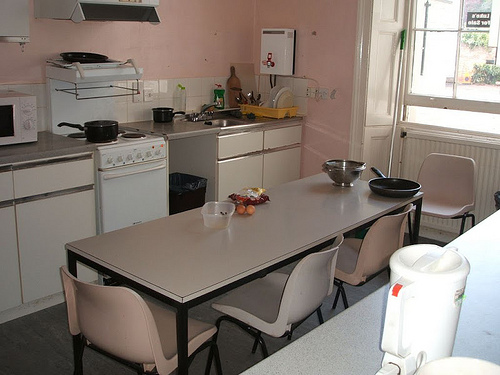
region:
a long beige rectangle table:
[55, 166, 412, 316]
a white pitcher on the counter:
[362, 227, 471, 366]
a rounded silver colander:
[314, 146, 366, 192]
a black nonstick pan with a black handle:
[365, 158, 432, 202]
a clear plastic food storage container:
[191, 196, 242, 233]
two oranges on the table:
[237, 201, 255, 217]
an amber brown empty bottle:
[220, 60, 247, 113]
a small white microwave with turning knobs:
[2, 87, 47, 149]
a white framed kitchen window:
[414, 2, 494, 128]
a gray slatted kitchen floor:
[16, 319, 56, 364]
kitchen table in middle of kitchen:
[57, 155, 419, 353]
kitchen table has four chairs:
[49, 156, 479, 351]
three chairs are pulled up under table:
[50, 193, 417, 355]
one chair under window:
[407, 154, 477, 228]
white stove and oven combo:
[47, 62, 175, 227]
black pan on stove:
[56, 118, 119, 141]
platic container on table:
[200, 200, 236, 229]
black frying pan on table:
[367, 163, 420, 198]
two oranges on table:
[235, 204, 257, 214]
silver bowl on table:
[321, 157, 366, 189]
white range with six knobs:
[65, 123, 170, 287]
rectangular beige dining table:
[55, 167, 426, 372]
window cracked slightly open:
[392, 8, 497, 147]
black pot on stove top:
[53, 112, 122, 144]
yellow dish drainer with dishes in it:
[234, 90, 300, 125]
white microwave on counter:
[2, 85, 44, 153]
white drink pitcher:
[371, 237, 471, 374]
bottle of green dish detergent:
[210, 82, 227, 112]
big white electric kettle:
[381, 256, 469, 371]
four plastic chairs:
[50, 141, 478, 372]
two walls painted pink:
[0, 1, 358, 180]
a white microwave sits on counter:
[0, 85, 44, 151]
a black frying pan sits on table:
[60, 157, 425, 374]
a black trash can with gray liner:
[162, 160, 210, 220]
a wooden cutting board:
[220, 57, 247, 111]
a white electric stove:
[42, 52, 177, 247]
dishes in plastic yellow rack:
[230, 82, 302, 124]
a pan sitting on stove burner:
[36, 46, 166, 293]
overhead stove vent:
[29, 0, 166, 32]